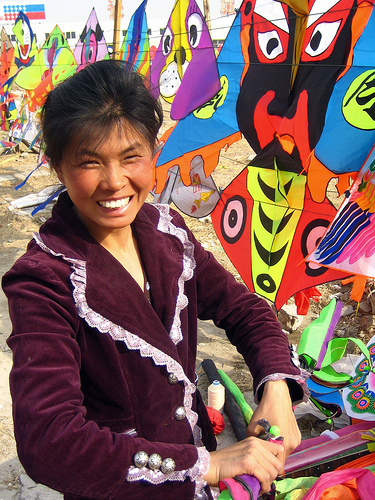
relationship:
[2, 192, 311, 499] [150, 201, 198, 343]
coat has white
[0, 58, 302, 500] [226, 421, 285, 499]
woman folding kite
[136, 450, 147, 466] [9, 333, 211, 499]
button on sleeve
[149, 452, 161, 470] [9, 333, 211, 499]
button on sleeve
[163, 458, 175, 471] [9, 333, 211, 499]
button on sleeve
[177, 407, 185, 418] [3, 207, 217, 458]
button on front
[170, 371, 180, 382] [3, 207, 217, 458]
button on front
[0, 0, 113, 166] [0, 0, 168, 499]
kites on left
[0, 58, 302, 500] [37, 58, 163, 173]
woman has hair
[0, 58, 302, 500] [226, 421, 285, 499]
woman holding kite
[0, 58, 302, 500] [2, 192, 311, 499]
woman has coat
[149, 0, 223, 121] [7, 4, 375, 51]
kite tied to rope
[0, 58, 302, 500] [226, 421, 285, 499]
woman selling kite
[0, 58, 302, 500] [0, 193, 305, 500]
woman wearing dress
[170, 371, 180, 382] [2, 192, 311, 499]
button in coat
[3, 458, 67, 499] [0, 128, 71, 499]
shadow on ground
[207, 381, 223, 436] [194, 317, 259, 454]
bottle on ground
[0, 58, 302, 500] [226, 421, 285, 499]
woman rolling kite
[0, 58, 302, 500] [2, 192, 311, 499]
woman wearing blouse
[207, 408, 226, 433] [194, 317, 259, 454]
twine on ground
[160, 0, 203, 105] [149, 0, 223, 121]
face on kite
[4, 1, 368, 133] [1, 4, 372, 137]
building in background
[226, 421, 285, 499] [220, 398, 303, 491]
kite in hands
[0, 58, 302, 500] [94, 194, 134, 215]
woman with smile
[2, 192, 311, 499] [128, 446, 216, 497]
coat with trim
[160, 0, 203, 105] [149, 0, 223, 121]
face of dog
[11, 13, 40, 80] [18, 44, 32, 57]
cyclops with lips